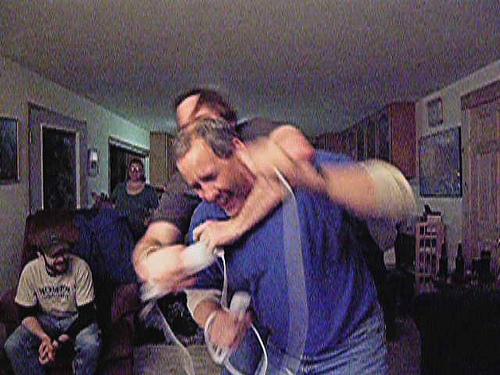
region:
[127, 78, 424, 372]
two men wrestling in living room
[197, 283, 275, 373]
hand holding white video game controller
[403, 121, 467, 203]
black framed picture on wall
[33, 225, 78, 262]
black baseball cap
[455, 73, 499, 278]
door in living room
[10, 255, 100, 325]
tan short sleeve t-shirt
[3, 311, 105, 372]
pair of blue jeans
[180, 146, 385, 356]
blue short sleeve t-shirt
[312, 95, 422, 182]
brown cabinets on wall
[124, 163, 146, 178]
eye glasses on face of woman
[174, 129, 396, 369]
this is a person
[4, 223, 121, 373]
this is a person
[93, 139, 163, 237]
this is a person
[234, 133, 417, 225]
this is a hand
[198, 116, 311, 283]
this is a hand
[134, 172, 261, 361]
this is a hand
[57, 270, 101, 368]
this is a hand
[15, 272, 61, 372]
this is a hand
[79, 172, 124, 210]
this is a hand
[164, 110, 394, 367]
this is a man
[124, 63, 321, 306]
this is a man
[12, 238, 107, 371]
this is a man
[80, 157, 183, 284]
this is a man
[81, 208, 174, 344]
this is a man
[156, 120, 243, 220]
the head of a person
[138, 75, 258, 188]
the head of a person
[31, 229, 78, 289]
the head of a person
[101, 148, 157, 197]
the head of a person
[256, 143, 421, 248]
the hand of a person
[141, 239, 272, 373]
white video game controllers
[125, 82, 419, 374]
two men wrestling while playing a video game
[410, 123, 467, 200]
black framed picture of USA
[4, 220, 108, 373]
man sitting down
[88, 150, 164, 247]
woman in green shirt standing up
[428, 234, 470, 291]
two dark colored bottles on table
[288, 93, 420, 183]
brown upper kitchen cupboards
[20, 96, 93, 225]
doorway that is cracked open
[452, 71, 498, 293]
closed tan colored door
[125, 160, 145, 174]
glasses with glare on the lenses